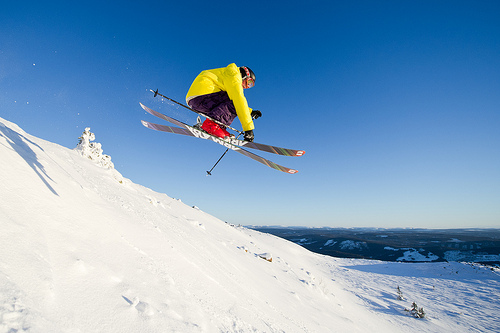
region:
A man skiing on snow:
[160, 45, 313, 160]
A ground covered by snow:
[49, 256, 163, 332]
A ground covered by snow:
[158, 216, 311, 312]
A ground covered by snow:
[7, 141, 112, 299]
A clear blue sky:
[7, 2, 119, 130]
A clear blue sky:
[126, 6, 266, 48]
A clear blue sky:
[290, 25, 423, 112]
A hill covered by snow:
[390, 245, 432, 267]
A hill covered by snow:
[329, 224, 364, 262]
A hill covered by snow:
[433, 226, 479, 260]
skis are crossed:
[145, 91, 316, 192]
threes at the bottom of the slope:
[383, 279, 434, 327]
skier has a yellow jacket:
[178, 56, 282, 143]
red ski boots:
[198, 113, 228, 145]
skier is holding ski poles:
[133, 64, 261, 183]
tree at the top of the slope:
[65, 109, 119, 181]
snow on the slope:
[87, 211, 234, 309]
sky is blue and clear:
[70, 15, 270, 58]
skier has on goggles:
[239, 66, 258, 91]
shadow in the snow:
[9, 108, 76, 212]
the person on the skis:
[117, 40, 330, 187]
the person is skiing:
[132, 55, 317, 191]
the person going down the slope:
[133, 44, 309, 171]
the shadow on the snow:
[1, 118, 56, 177]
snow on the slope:
[18, 144, 363, 319]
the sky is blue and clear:
[6, 0, 498, 139]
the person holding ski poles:
[172, 54, 277, 169]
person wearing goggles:
[238, 63, 255, 80]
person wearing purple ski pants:
[189, 91, 255, 135]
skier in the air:
[132, 51, 329, 192]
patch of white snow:
[153, 224, 179, 250]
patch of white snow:
[123, 250, 148, 276]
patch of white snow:
[349, 311, 369, 327]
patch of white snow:
[94, 300, 131, 330]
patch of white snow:
[105, 260, 138, 290]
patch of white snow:
[91, 245, 128, 273]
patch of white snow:
[363, 293, 397, 324]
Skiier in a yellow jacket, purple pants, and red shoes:
[136, 62, 308, 174]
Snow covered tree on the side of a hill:
[68, 125, 119, 175]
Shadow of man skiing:
[3, 123, 61, 196]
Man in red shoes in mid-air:
[141, 63, 306, 173]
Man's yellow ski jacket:
[187, 61, 257, 132]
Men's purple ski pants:
[188, 89, 239, 127]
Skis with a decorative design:
[136, 101, 305, 175]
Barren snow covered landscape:
[326, 226, 499, 261]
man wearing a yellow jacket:
[191, 58, 258, 138]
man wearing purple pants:
[185, 93, 236, 122]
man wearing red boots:
[198, 115, 230, 142]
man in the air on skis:
[126, 52, 316, 197]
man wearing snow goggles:
[245, 74, 258, 86]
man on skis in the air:
[130, 98, 304, 181]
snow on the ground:
[44, 211, 238, 330]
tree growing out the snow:
[393, 278, 408, 302]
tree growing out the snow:
[406, 295, 419, 319]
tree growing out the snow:
[417, 303, 426, 318]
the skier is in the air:
[142, 64, 308, 177]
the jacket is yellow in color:
[185, 63, 257, 131]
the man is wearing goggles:
[241, 64, 256, 88]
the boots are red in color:
[199, 115, 229, 139]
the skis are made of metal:
[138, 100, 298, 177]